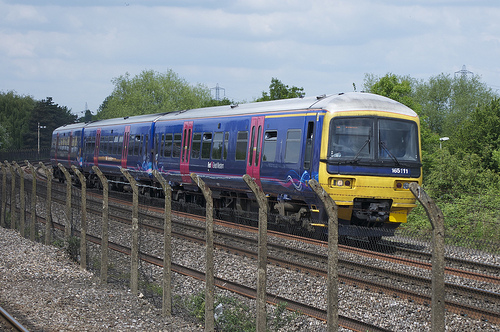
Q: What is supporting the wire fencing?
A: Poles.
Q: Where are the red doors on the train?
A: On the side.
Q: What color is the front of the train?
A: Yellow.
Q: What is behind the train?
A: Trees.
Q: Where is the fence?
A: Beside the railroad tracks.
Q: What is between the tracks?
A: Gravel.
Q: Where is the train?
A: On the railroad tracks.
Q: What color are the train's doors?
A: Red.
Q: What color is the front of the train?
A: Yellow.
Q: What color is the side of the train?
A: Blue.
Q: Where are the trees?
A: Behind the train.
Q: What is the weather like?
A: Cloudy.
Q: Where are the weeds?
A: Beside the fence.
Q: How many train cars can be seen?
A: Three.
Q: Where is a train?
A: On train tracks.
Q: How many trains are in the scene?
A: One.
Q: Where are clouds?
A: In the sky.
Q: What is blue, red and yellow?
A: The train.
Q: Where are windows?
A: On the train.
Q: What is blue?
A: Sky.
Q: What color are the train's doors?
A: Red.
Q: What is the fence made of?
A: Metal.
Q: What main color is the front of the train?
A: Yellow.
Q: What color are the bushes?
A: Green.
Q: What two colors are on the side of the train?
A: Blue and Red.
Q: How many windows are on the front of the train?
A: Two.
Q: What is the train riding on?
A: Tracks.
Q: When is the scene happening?
A: Daytime.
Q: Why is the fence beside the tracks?
A: To keep people off of the tracks.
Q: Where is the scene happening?
A: Countryside.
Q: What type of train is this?
A: Passenger.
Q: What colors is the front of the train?
A: Yellow and blue.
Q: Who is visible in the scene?
A: No one.